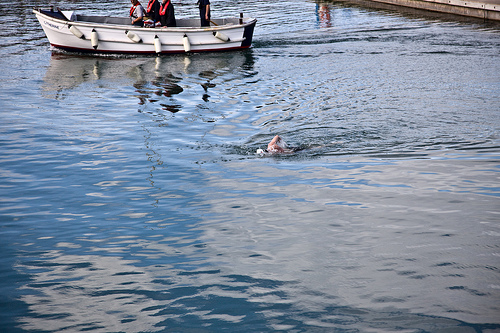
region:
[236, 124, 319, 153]
a person in the water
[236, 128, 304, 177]
a swimmer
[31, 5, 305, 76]
a white boat in the water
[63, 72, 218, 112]
waves of the water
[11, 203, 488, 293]
the blue water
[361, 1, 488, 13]
a dock in the background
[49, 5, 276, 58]
people in a boat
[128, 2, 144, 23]
a person in a red life vest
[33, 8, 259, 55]
a boat in the water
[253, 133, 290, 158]
a person wearing a white cap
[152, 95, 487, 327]
the man is in the water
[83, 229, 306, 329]
the water is rough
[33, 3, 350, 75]
the boat is white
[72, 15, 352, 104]
buoys are on the boat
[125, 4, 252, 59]
people are in the boat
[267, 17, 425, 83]
the reflection is in the water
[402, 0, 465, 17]
the dock is by the water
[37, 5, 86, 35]
the boat has black writing on the boat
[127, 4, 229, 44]
people are wearing life vests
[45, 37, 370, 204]
the boat's reflection is in the water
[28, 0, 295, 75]
people in the boat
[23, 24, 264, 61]
white color boat in the water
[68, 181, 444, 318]
small waves in the water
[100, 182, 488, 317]
blue color sea water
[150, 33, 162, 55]
gunports of the boat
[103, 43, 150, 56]
lower wale of the boat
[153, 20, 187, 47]
main or spare deck of the boat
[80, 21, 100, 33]
quarter deck of the boat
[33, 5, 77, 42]
poop deck of the boat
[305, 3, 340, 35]
people reflection in the water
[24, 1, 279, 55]
this is a boat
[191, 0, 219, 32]
a person inside the water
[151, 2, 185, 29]
a person inside the water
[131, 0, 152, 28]
a person inside the water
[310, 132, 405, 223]
the water is calm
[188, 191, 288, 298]
the water is calm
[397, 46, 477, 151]
the water is calm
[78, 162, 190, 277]
the water is calm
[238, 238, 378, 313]
the water is calm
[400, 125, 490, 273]
the water is calm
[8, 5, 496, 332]
The water beneath the boat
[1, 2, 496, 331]
The water is calm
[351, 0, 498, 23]
A dock behind the boat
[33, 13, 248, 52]
A boat on the water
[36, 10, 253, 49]
The small boat is white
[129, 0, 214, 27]
People standing in the boat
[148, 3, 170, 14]
The people are wearing life preservers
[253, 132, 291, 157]
An object in the water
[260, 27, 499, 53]
A trail behind the boat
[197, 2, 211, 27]
The person is wearing black clothing